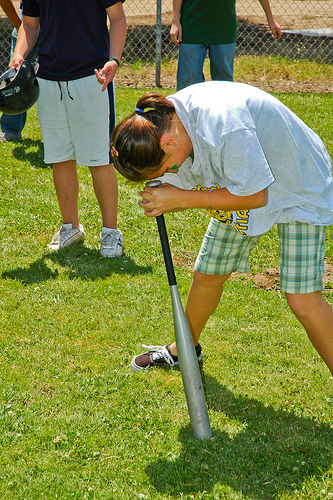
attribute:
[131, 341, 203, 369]
shoes — brown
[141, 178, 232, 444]
bat — silver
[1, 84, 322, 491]
grass — green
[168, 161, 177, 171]
paint — green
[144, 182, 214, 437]
baseball bat — grey, metal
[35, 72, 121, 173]
shorts — blue and white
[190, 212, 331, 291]
shorts — plaid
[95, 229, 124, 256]
shoe — white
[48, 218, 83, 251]
shoe — white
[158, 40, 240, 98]
jeans — loose fitting, denim, blue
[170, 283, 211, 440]
metal — shiny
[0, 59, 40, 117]
helmet — black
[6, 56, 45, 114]
helmet — shiny, black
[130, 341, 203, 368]
sneaker — brown and white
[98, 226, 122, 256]
sneaker — brown and white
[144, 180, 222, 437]
bat — steel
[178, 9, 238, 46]
shirt — green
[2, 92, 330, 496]
field — grass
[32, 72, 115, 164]
shorts — white and blue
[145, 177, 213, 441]
bat — shiny, silver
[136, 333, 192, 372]
shoe laces — white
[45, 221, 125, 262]
shoes — old, white, tennis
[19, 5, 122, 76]
tee shirt — blue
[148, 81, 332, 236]
tee shirt — gray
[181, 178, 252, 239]
writing — black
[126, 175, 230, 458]
baseball bat — aluminum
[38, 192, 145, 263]
shoes — white, tennis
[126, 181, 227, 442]
bat — baseball, silver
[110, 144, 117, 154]
barette — orange, hair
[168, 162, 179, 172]
paint — green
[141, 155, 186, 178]
face — woman's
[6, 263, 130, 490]
grass field — green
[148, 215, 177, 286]
handle — black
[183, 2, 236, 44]
tee shirt — hunter green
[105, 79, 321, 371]
woman — healthy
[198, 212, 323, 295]
short pants — plaid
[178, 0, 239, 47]
tee shirt — green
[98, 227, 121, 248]
laces — white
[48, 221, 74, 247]
laces — white